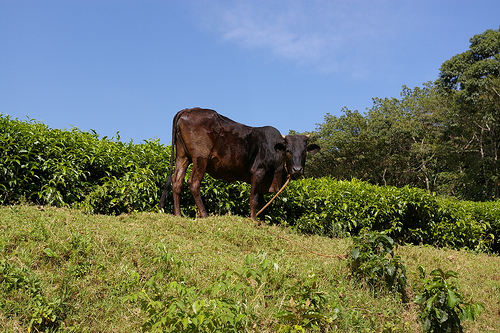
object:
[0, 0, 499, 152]
cloud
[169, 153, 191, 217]
legs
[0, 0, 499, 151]
sky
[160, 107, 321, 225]
cow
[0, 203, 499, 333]
dirt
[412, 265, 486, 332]
plant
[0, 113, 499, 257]
hedge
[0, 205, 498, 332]
grass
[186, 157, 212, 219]
leg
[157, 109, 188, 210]
tail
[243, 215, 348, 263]
rope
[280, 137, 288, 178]
cows neck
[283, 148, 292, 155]
eye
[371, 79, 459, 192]
trees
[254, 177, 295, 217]
rope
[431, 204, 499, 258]
bushes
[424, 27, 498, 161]
trees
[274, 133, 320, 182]
head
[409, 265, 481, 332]
bushes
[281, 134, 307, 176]
face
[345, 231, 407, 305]
bush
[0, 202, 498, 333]
field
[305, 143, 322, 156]
ear